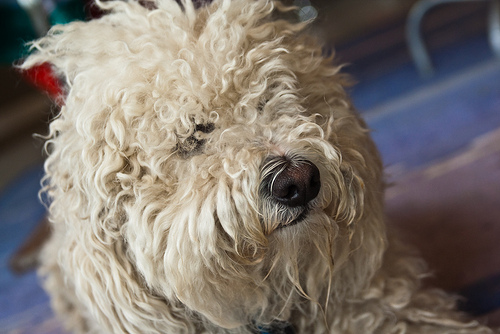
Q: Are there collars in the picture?
A: Yes, there is a collar.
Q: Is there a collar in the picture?
A: Yes, there is a collar.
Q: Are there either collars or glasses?
A: Yes, there is a collar.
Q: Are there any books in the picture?
A: No, there are no books.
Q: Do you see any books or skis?
A: No, there are no books or skis.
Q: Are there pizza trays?
A: No, there are no pizza trays.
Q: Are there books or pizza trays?
A: No, there are no pizza trays or books.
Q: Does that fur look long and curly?
A: Yes, the fur is long and curly.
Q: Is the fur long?
A: Yes, the fur is long.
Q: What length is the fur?
A: The fur is long.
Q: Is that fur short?
A: No, the fur is long.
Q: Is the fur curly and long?
A: Yes, the fur is curly and long.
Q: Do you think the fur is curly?
A: Yes, the fur is curly.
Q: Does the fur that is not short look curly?
A: Yes, the fur is curly.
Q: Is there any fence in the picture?
A: No, there are no fences.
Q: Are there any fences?
A: No, there are no fences.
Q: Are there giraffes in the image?
A: No, there are no giraffes.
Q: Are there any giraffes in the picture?
A: No, there are no giraffes.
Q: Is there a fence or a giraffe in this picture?
A: No, there are no giraffes or fences.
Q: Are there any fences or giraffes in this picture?
A: No, there are no giraffes or fences.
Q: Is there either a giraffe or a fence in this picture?
A: No, there are no giraffes or fences.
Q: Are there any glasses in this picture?
A: No, there are no glasses.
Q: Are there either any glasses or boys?
A: No, there are no glasses or boys.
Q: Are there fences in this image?
A: No, there are no fences.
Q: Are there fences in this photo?
A: No, there are no fences.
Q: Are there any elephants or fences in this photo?
A: No, there are no fences or elephants.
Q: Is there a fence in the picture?
A: No, there are no fences.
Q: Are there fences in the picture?
A: No, there are no fences.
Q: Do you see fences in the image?
A: No, there are no fences.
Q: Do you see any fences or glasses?
A: No, there are no fences or glasses.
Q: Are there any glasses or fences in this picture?
A: No, there are no fences or glasses.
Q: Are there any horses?
A: No, there are no horses.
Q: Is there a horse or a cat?
A: No, there are no horses or cats.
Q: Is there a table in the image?
A: Yes, there is a table.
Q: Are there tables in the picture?
A: Yes, there is a table.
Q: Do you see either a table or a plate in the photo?
A: Yes, there is a table.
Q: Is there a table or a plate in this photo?
A: Yes, there is a table.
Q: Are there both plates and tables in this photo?
A: No, there is a table but no plates.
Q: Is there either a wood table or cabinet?
A: Yes, there is a wood table.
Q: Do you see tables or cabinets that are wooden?
A: Yes, the table is wooden.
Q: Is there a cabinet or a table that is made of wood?
A: Yes, the table is made of wood.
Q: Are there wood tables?
A: Yes, there is a wood table.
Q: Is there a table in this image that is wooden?
A: Yes, there is a table that is wooden.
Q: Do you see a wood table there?
A: Yes, there is a table that is made of wood.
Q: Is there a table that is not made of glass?
A: Yes, there is a table that is made of wood.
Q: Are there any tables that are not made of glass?
A: Yes, there is a table that is made of wood.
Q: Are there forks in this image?
A: No, there are no forks.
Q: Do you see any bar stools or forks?
A: No, there are no forks or bar stools.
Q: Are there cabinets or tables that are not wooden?
A: No, there is a table but it is wooden.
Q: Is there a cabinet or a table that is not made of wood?
A: No, there is a table but it is made of wood.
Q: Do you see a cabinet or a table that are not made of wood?
A: No, there is a table but it is made of wood.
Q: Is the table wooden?
A: Yes, the table is wooden.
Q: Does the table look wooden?
A: Yes, the table is wooden.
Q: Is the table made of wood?
A: Yes, the table is made of wood.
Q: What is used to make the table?
A: The table is made of wood.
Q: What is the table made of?
A: The table is made of wood.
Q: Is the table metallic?
A: No, the table is wooden.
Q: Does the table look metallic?
A: No, the table is wooden.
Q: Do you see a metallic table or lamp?
A: No, there is a table but it is wooden.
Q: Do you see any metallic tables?
A: No, there is a table but it is wooden.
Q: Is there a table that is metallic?
A: No, there is a table but it is wooden.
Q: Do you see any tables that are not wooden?
A: No, there is a table but it is wooden.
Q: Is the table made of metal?
A: No, the table is made of wood.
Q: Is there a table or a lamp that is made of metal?
A: No, there is a table but it is made of wood.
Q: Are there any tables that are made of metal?
A: No, there is a table but it is made of wood.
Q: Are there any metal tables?
A: No, there is a table but it is made of wood.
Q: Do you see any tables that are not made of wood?
A: No, there is a table but it is made of wood.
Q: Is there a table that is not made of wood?
A: No, there is a table but it is made of wood.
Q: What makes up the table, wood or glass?
A: The table is made of wood.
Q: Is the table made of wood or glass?
A: The table is made of wood.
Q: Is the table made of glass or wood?
A: The table is made of wood.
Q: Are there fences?
A: No, there are no fences.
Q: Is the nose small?
A: Yes, the nose is small.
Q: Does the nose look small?
A: Yes, the nose is small.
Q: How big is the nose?
A: The nose is small.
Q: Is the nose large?
A: No, the nose is small.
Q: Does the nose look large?
A: No, the nose is small.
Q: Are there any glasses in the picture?
A: No, there are no glasses.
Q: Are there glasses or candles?
A: No, there are no glasses or candles.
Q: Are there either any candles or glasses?
A: No, there are no glasses or candles.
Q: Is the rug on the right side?
A: Yes, the rug is on the right of the image.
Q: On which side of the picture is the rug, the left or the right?
A: The rug is on the right of the image.